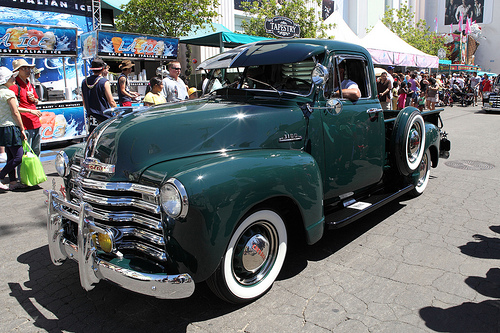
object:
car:
[43, 38, 450, 306]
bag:
[19, 139, 48, 187]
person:
[0, 64, 33, 191]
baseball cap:
[89, 60, 106, 71]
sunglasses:
[171, 67, 181, 70]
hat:
[11, 58, 36, 73]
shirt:
[80, 74, 112, 119]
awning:
[102, 0, 277, 49]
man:
[324, 58, 362, 101]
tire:
[391, 105, 426, 176]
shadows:
[419, 221, 500, 333]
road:
[0, 96, 500, 333]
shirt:
[8, 75, 43, 130]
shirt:
[0, 86, 21, 128]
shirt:
[324, 78, 359, 91]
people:
[374, 70, 500, 112]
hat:
[0, 66, 20, 86]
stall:
[0, 0, 180, 145]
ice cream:
[1, 0, 180, 148]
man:
[80, 55, 116, 137]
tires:
[207, 209, 288, 306]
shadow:
[8, 190, 422, 332]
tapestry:
[269, 22, 296, 32]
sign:
[264, 16, 300, 39]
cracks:
[0, 171, 500, 333]